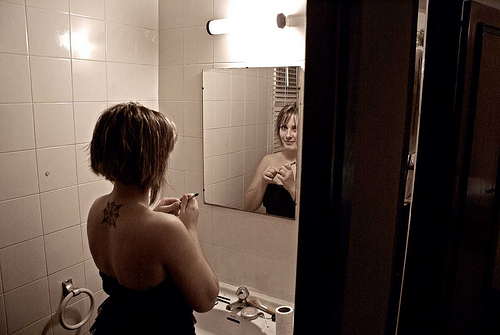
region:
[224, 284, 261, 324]
Faucet in modern bathroom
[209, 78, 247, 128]
Mirror in modern bathroom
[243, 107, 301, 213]
Reflection of young woman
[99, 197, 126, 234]
Tattoo of young woman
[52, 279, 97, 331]
Modern towel ring holder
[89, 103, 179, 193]
Head of young woman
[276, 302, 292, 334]
Roll of toilet tissue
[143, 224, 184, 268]
Shoulder of young woman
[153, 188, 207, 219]
Hands of young woman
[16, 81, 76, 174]
Tile on modern bathroom wall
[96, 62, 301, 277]
a woman standing in front of a mirror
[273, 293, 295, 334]
a roll of toilet paper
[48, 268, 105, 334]
a round towel holder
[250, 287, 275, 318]
a make up brush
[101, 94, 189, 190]
a woman with short hair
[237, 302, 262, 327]
a make up compact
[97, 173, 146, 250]
a woman with a tatoo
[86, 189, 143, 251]
a woman with a tatoo on her back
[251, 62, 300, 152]
a reflection of a window in the mirror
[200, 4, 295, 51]
a light over a mirror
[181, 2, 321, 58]
"The light is on"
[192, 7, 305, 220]
"There is a light over a the mirror"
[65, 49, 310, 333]
"She is looking at herself in the mirror"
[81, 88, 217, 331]
"She has a tattoo on her back"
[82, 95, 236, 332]
"The lady is wearing a black dress"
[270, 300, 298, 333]
"A roll of toilet tissue is pictured here"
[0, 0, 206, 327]
"The wall is tiled"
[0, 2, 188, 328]
"The tiles are white"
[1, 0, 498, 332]
"The lady is in the bathroom"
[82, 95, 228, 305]
"She is holding something in her hands"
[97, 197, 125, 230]
Tattoo on woman's back.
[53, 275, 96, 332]
Towel holder on the side of the wall.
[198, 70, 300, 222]
Mirror on the wall.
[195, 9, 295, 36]
Light on the wall.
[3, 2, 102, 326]
White tiles on the wall.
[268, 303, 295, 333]
Toilet paper on the sink.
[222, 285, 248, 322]
Silver faucet on the sink.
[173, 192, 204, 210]
Makeup brush in her hand.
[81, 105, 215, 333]
Black dress on the woman.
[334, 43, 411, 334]
Brown wooden door jamb.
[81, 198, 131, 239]
Tattoo on the back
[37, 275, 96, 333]
Metal hanger on wall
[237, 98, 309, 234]
Womans reflection in the mirror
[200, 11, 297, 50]
Bery bright light on the wall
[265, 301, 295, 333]
Toilet paper on the sink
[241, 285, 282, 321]
Makeup brush sitting on the sink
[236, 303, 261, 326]
Circle compact sitting on the sink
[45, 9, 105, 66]
Reflection of the light on the tile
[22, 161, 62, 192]
Painted over screw on wall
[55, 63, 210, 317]
Woman standing